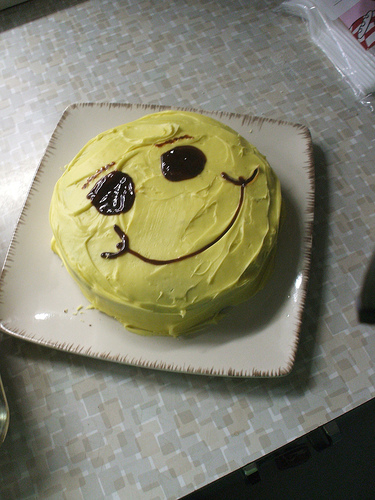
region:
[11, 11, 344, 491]
a cake on a plate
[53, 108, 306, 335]
a cake shaped like a smiley face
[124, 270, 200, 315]
yellow buttercream frosting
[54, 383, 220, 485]
a formica counter top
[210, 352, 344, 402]
a plate with brown decorative edge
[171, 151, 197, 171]
brown gel frosting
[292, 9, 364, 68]
a packet of plastic forks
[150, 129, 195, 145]
the eyebrow of a smiley face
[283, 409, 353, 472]
the handle for a cabinet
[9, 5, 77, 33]
a shadow on a countertop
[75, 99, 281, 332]
the cake on the tray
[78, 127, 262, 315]
the cake is smiley face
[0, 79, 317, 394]
the tray is square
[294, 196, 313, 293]
the edge of the tray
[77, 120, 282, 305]
frosting on the cake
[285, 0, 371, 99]
forks on the counter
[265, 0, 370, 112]
the forks are plastic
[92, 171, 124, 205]
the eye on the cake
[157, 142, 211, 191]
the eye on cake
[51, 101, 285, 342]
Cake on the table.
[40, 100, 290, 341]
Smiley face on the cake.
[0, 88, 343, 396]
Square plate on the table.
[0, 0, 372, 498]
Brown and white table.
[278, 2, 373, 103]
Plastic forks on the table.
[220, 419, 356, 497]
Metal bracket on the table.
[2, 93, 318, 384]
Brown design on the edge of the plate.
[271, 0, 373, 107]
Plastic bag holding the forks.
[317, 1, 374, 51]
Label on the bag.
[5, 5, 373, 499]
Squares of brown and gray pattern.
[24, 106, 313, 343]
cake sitting on a plate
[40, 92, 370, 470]
plate sitting on the table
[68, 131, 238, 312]
cake has yellow frosting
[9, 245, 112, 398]
the plate is white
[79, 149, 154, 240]
face made of black icing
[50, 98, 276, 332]
the cake is round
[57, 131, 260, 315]
cake has smiley face on it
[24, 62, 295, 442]
plate is rectangular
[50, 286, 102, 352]
crumbs on the plate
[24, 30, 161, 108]
pattern on the table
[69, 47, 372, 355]
a cake on a plate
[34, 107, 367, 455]
a cake on a table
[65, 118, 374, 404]
a cake on a white plate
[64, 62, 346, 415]
a cake on a square plate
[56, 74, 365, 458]
a round cake on a plate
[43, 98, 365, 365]
a plate with a cake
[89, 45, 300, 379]
a plate with a round cake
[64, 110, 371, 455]
a smiley face cake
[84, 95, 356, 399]
a yellow cake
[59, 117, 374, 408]
a yellow cake on a palte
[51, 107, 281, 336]
large yellow smiley face cake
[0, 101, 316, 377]
square plate with brown edges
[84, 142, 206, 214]
two chocolate circles on a cake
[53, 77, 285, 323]
A piece of food.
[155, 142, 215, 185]
A piece of food.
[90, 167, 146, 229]
A piece of food.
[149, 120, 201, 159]
A piece of food.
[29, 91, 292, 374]
A piece of food.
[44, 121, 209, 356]
A piece of food.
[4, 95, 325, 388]
A plate made for dining.